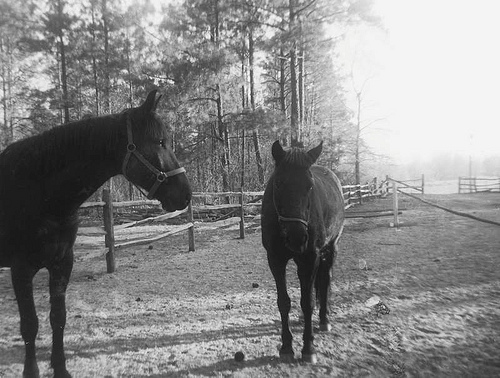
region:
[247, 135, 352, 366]
A horse looking towards the camera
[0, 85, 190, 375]
A horse looking away from the camera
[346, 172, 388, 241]
A section of split rail fence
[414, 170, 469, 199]
An open gateway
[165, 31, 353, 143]
Trees at the edge of the fence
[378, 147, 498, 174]
Trees in the distant background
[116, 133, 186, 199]
A horse halter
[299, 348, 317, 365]
A horse hoof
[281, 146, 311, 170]
A horse forelock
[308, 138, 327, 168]
The ear of a horse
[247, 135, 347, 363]
The smaller of the two horses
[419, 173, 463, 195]
The gap in the fence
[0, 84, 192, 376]
The larger of the two horses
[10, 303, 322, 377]
The shadow of the smaller horse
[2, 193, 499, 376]
The dirt field the horses are in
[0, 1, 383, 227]
The trees in the background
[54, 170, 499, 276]
The fence to the field the horses are in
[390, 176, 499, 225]
The two horizontal logs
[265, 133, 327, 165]
The ears of the shorter horse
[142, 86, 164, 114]
The ears of the larger horse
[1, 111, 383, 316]
Two horses on the farm.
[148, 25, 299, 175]
Tall trees in the background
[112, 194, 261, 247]
Wooden fence along side the field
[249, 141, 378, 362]
The horse is brown.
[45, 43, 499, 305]
The photo is black and white.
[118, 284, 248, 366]
The ground has dirt.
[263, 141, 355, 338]
The horse is watching the camera.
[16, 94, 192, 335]
The horse is looking at the other horse.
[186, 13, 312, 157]
The tree has little leaves.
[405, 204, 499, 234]
A log on the ground.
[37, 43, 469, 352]
black and white photograph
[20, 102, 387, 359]
two dark horses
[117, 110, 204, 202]
reigns around horses head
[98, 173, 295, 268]
long wooden fence along horses pen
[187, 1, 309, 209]
tall trees in the background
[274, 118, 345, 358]
horse looking directly at camera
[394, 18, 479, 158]
bright sunlight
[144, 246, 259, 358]
grass and dirt field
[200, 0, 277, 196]
trees with few leaves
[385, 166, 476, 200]
opening in the wooden fence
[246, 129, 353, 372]
Black horse on the right.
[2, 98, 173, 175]
Left horses' mane.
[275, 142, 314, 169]
Right black horses' man.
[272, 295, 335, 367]
Right horses' hooves.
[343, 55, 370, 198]
Single dead tree in background.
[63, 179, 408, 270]
Nearest fence line.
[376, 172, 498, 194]
Open fence without a gate.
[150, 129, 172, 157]
Left horses' right eye.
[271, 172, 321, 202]
Right horses' two eyes.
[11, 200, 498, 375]
Horses dirt-covered pen with feces